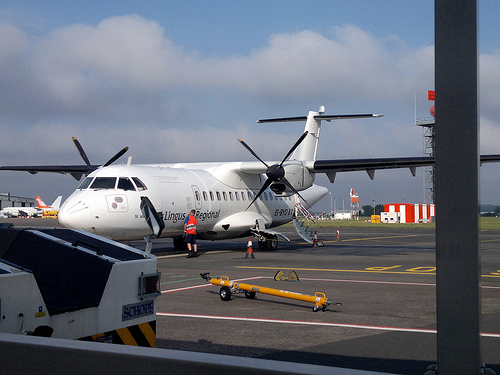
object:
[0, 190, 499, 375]
airfield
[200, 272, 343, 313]
pole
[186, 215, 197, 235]
orange vest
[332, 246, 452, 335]
tarmac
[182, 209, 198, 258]
man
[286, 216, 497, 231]
grass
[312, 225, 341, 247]
traffic cones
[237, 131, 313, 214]
propeller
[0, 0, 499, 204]
sky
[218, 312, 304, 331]
line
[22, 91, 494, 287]
gear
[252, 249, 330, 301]
blocks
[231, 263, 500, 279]
yellow line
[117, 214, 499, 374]
ground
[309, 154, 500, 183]
wing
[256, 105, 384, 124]
stabilizer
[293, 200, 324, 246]
plane's staircase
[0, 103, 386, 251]
aircraft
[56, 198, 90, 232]
nose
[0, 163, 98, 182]
wing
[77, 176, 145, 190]
window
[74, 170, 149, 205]
cockpit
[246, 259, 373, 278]
line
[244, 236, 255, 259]
cone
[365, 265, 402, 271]
p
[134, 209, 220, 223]
words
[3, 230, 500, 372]
runway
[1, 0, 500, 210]
clouds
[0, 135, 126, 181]
propeller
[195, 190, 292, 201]
porthole windows